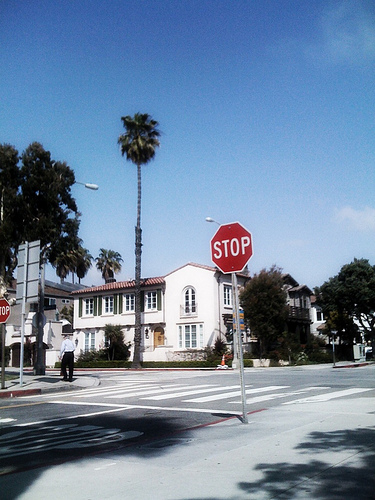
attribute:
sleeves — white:
[59, 337, 80, 354]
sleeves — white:
[46, 320, 105, 369]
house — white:
[143, 270, 228, 379]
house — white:
[141, 250, 226, 350]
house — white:
[161, 272, 240, 368]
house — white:
[141, 270, 273, 385]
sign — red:
[225, 188, 289, 300]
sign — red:
[205, 217, 237, 246]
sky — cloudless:
[1, 0, 294, 104]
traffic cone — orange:
[219, 353, 227, 365]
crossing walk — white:
[17, 384, 355, 417]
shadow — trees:
[231, 425, 362, 495]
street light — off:
[71, 179, 100, 193]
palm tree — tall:
[117, 112, 159, 369]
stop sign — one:
[209, 221, 251, 422]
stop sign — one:
[0, 297, 9, 389]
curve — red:
[143, 365, 218, 371]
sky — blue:
[259, 3, 363, 251]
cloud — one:
[330, 198, 363, 241]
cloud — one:
[270, 5, 364, 71]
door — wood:
[152, 328, 162, 348]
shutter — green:
[96, 296, 102, 315]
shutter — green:
[117, 292, 123, 313]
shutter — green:
[157, 286, 161, 311]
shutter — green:
[156, 289, 163, 309]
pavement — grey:
[21, 429, 355, 498]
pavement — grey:
[17, 422, 355, 498]